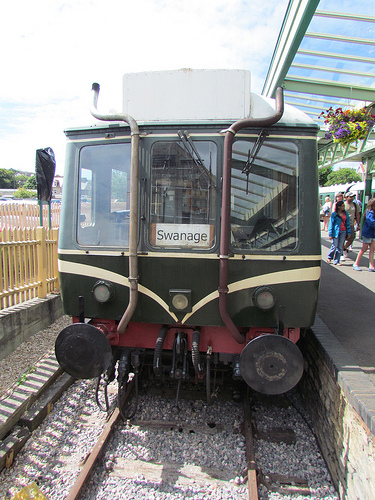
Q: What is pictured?
A: Train.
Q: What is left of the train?
A: Fence.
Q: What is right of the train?
A: Group of people.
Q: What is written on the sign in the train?
A: Swanage.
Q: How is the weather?
A: Partly cloudy.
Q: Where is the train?
A: At the station.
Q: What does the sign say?
A: Swanage.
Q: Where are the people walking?
A: On the platform.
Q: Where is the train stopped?
A: At a station.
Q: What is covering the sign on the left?
A: A black plastic bag.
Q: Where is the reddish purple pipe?
A: On the right front of the train.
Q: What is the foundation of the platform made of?
A: Brick.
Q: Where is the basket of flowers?
A: Hanging from the overhang.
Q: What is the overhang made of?
A: Metal and glass.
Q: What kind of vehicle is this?
A: Train.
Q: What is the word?
A: Swanage.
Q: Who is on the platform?
A: Passengers.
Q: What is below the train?
A: Tracks.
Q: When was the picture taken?
A: During the day.